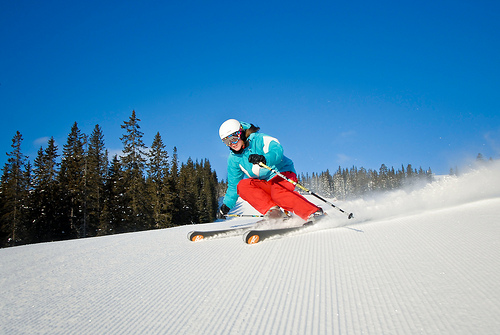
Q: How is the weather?
A: It is cloudless.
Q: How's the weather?
A: It is cloudless.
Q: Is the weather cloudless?
A: Yes, it is cloudless.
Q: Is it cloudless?
A: Yes, it is cloudless.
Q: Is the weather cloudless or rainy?
A: It is cloudless.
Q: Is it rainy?
A: No, it is cloudless.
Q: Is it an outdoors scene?
A: Yes, it is outdoors.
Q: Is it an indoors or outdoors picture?
A: It is outdoors.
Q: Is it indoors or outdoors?
A: It is outdoors.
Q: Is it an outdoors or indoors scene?
A: It is outdoors.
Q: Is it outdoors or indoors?
A: It is outdoors.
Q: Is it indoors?
A: No, it is outdoors.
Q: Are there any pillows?
A: No, there are no pillows.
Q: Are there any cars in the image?
A: No, there are no cars.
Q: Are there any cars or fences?
A: No, there are no cars or fences.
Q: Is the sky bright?
A: Yes, the sky is bright.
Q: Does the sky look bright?
A: Yes, the sky is bright.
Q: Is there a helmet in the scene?
A: Yes, there is a helmet.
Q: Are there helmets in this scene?
A: Yes, there is a helmet.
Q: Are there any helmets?
A: Yes, there is a helmet.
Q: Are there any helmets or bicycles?
A: Yes, there is a helmet.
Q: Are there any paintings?
A: No, there are no paintings.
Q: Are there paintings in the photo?
A: No, there are no paintings.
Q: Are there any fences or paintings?
A: No, there are no paintings or fences.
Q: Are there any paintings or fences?
A: No, there are no paintings or fences.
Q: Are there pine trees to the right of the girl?
A: Yes, there are pine trees to the right of the girl.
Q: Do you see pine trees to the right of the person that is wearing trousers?
A: Yes, there are pine trees to the right of the girl.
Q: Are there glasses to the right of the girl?
A: No, there are pine trees to the right of the girl.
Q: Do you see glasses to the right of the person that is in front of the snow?
A: No, there are pine trees to the right of the girl.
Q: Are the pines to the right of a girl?
A: Yes, the pines are to the right of a girl.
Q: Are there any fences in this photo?
A: No, there are no fences.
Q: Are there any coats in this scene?
A: Yes, there is a coat.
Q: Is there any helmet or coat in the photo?
A: Yes, there is a coat.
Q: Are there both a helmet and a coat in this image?
A: Yes, there are both a coat and a helmet.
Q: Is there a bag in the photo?
A: No, there are no bags.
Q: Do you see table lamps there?
A: No, there are no table lamps.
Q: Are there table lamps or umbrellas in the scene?
A: No, there are no table lamps or umbrellas.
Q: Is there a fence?
A: No, there are no fences.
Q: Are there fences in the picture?
A: No, there are no fences.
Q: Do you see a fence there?
A: No, there are no fences.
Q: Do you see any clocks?
A: No, there are no clocks.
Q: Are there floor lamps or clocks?
A: No, there are no clocks or floor lamps.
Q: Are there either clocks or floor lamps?
A: No, there are no clocks or floor lamps.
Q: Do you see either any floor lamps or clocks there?
A: No, there are no clocks or floor lamps.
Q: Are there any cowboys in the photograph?
A: No, there are no cowboys.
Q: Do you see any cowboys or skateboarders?
A: No, there are no cowboys or skateboarders.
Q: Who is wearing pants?
A: The girl is wearing pants.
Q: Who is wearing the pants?
A: The girl is wearing pants.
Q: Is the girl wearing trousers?
A: Yes, the girl is wearing trousers.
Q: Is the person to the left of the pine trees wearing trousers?
A: Yes, the girl is wearing trousers.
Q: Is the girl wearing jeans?
A: No, the girl is wearing trousers.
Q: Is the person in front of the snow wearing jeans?
A: No, the girl is wearing trousers.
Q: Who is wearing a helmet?
A: The girl is wearing a helmet.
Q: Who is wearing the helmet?
A: The girl is wearing a helmet.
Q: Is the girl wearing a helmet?
A: Yes, the girl is wearing a helmet.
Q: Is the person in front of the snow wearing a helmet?
A: Yes, the girl is wearing a helmet.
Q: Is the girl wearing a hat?
A: No, the girl is wearing a helmet.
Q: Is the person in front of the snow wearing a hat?
A: No, the girl is wearing a helmet.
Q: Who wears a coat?
A: The girl wears a coat.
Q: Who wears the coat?
A: The girl wears a coat.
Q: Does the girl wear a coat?
A: Yes, the girl wears a coat.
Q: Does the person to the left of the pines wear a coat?
A: Yes, the girl wears a coat.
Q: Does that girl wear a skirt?
A: No, the girl wears a coat.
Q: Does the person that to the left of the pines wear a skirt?
A: No, the girl wears a coat.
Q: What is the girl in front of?
A: The girl is in front of the snow.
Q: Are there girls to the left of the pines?
A: Yes, there is a girl to the left of the pines.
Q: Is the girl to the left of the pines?
A: Yes, the girl is to the left of the pines.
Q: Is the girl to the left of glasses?
A: No, the girl is to the left of the pines.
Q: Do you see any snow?
A: Yes, there is snow.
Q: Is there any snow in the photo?
A: Yes, there is snow.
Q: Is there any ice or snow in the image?
A: Yes, there is snow.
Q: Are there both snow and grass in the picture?
A: No, there is snow but no grass.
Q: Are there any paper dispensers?
A: No, there are no paper dispensers.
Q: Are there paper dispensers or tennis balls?
A: No, there are no paper dispensers or tennis balls.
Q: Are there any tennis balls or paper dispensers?
A: No, there are no paper dispensers or tennis balls.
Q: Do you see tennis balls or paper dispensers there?
A: No, there are no paper dispensers or tennis balls.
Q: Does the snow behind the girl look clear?
A: Yes, the snow is clear.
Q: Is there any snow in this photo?
A: Yes, there is snow.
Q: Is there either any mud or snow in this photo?
A: Yes, there is snow.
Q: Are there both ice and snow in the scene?
A: No, there is snow but no ice.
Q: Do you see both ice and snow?
A: No, there is snow but no ice.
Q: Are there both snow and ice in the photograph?
A: No, there is snow but no ice.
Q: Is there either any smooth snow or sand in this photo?
A: Yes, there is smooth snow.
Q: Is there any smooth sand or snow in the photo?
A: Yes, there is smooth snow.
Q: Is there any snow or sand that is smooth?
A: Yes, the snow is smooth.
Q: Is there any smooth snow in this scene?
A: Yes, there is smooth snow.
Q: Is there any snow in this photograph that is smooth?
A: Yes, there is snow that is smooth.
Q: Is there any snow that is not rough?
A: Yes, there is smooth snow.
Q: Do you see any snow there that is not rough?
A: Yes, there is smooth snow.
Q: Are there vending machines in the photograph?
A: No, there are no vending machines.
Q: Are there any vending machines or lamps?
A: No, there are no vending machines or lamps.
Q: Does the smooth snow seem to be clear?
A: Yes, the snow is clear.